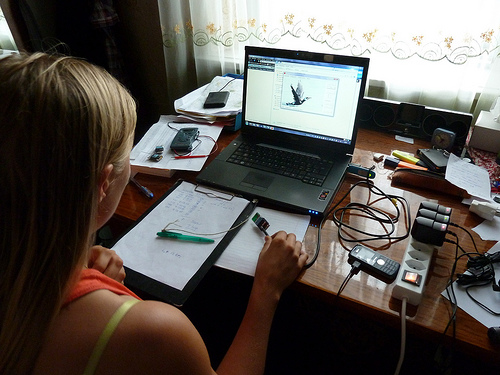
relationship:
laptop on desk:
[233, 37, 358, 221] [128, 63, 498, 321]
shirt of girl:
[64, 269, 143, 299] [3, 66, 273, 369]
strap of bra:
[101, 289, 129, 352] [104, 294, 131, 350]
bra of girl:
[104, 294, 131, 350] [3, 66, 273, 369]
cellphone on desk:
[345, 243, 396, 275] [128, 63, 498, 321]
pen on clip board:
[158, 224, 218, 244] [130, 172, 241, 295]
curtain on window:
[195, 3, 498, 102] [179, 1, 498, 124]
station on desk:
[394, 98, 427, 129] [128, 63, 498, 321]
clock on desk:
[431, 127, 450, 147] [128, 63, 498, 321]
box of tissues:
[464, 103, 498, 149] [490, 110, 498, 120]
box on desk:
[464, 103, 498, 149] [128, 63, 498, 321]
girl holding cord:
[3, 66, 273, 369] [257, 216, 321, 259]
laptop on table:
[233, 37, 358, 221] [135, 71, 474, 321]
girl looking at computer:
[3, 43, 310, 368] [224, 34, 352, 199]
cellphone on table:
[345, 243, 396, 275] [135, 71, 474, 321]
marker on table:
[382, 153, 424, 170] [135, 71, 474, 321]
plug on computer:
[348, 159, 376, 186] [224, 34, 352, 199]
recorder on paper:
[169, 124, 201, 159] [147, 106, 207, 170]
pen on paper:
[158, 224, 218, 244] [147, 106, 207, 170]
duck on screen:
[291, 83, 306, 105] [245, 59, 356, 134]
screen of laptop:
[245, 59, 356, 134] [233, 37, 358, 221]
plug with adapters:
[406, 200, 432, 276] [410, 198, 448, 242]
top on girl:
[62, 273, 125, 303] [3, 66, 273, 369]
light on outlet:
[407, 270, 417, 280] [402, 208, 432, 289]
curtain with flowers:
[195, 3, 498, 102] [196, 11, 490, 50]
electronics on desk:
[223, 74, 465, 284] [128, 63, 498, 321]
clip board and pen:
[130, 172, 241, 295] [158, 224, 218, 244]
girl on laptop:
[3, 66, 273, 369] [233, 37, 358, 221]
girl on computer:
[3, 66, 273, 369] [224, 34, 352, 199]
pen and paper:
[158, 224, 218, 244] [147, 106, 207, 170]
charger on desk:
[249, 203, 269, 230] [128, 63, 498, 321]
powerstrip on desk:
[397, 194, 430, 293] [128, 63, 498, 321]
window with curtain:
[179, 1, 498, 124] [195, 3, 498, 102]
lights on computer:
[304, 204, 326, 221] [224, 34, 352, 199]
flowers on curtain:
[196, 11, 490, 50] [195, 3, 498, 102]